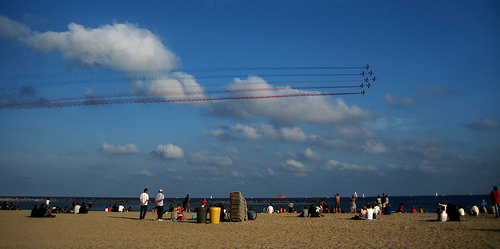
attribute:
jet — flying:
[366, 64, 369, 69]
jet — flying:
[360, 71, 365, 77]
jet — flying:
[369, 70, 373, 75]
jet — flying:
[370, 77, 375, 81]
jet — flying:
[365, 76, 368, 82]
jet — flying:
[367, 82, 371, 89]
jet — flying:
[359, 82, 363, 88]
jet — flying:
[361, 90, 365, 93]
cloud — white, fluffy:
[29, 19, 204, 112]